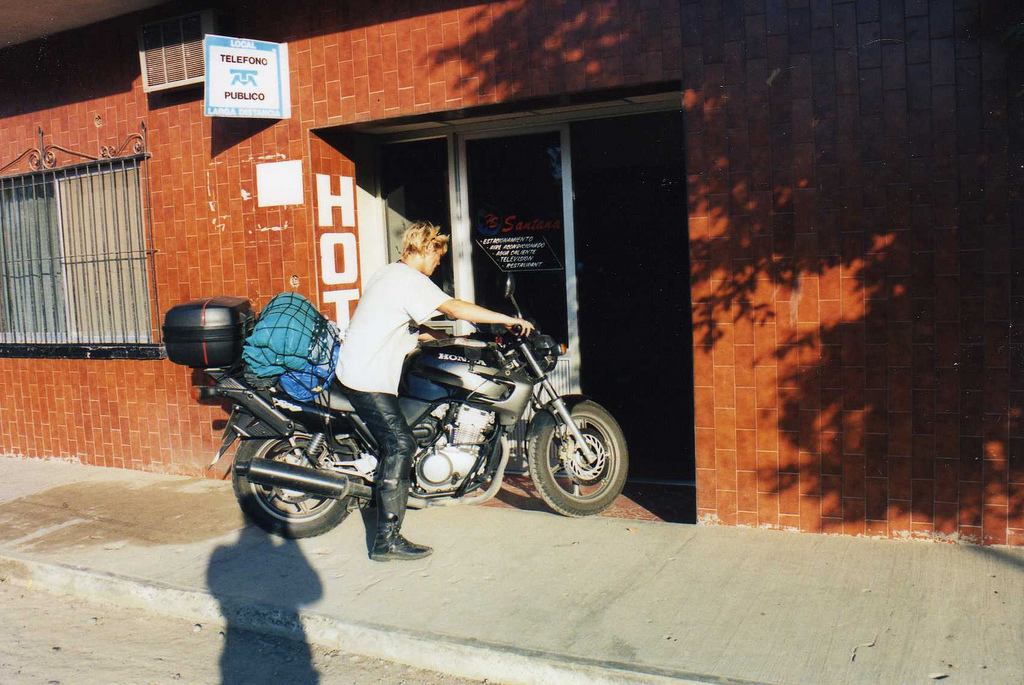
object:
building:
[0, 0, 1024, 548]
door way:
[370, 104, 695, 485]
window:
[0, 154, 154, 361]